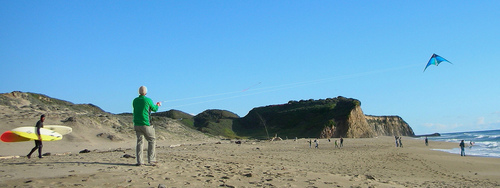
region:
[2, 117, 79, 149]
man carrying 2 surf boards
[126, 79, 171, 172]
man in green shirt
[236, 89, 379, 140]
cliff at edge of beach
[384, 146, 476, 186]
footprints in the sand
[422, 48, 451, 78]
blue kite flying in the air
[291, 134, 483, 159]
people playing on the beach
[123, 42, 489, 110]
man flying blue kite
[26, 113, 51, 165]
man in a wet suit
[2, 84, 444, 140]
hills surrounding the beach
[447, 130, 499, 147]
waves breaking into the beach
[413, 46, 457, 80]
large blue kite flying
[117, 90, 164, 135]
kelly green long sleeved shirt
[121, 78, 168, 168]
man wear khaki pants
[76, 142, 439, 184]
wide sany beach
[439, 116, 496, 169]
person stands at the shore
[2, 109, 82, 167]
surfer carries two surf boards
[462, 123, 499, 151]
small waves roll inot shore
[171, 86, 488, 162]
cliffs stand above the beach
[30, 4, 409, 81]
pleasent blue cloudless sky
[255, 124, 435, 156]
people walking on sandy beach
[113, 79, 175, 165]
Man wearing green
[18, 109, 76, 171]
Carrying two surfboards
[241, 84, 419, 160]
Cliffs beyond men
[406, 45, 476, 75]
Blue kite in sky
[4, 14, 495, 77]
Sky blue and clear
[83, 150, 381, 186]
Sand has footprints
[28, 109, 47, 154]
Man wearing black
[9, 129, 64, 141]
Surfboard is yellow and white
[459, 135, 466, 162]
Person standing in distance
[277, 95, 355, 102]
Grass on top of cliff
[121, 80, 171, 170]
man wearing green shirt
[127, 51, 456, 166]
ma flying kite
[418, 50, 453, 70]
blue kite flying in sky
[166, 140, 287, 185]
footprints in the sand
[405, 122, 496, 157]
blue and white waves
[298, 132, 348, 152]
people in the distance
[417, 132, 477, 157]
people near the water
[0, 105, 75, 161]
person carrying a surfboard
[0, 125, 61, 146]
yellow and orange surfboard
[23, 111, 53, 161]
person wearing dark clothing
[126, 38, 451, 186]
man wearing green shirt is flying blue kite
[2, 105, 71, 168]
man wearing black is carrying surfboards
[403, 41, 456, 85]
blue kite is in sky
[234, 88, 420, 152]
grass covered cliff is behind people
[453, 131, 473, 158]
man is standing near foamy water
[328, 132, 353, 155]
soupke is standing on brown beach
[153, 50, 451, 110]
white strings are attached to blue kite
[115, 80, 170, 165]
man flying kite is wearing khaki pants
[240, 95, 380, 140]
grass covered cliff is brown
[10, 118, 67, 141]
surfboard is yellow and white